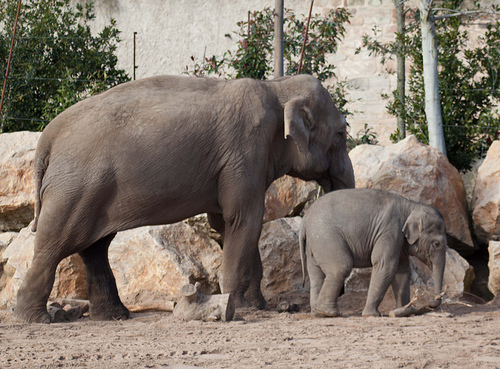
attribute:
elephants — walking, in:
[16, 72, 452, 322]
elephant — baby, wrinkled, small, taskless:
[299, 185, 448, 318]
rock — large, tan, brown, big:
[351, 135, 480, 254]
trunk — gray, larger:
[431, 259, 445, 308]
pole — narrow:
[133, 31, 136, 85]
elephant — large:
[11, 33, 357, 326]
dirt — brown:
[0, 309, 498, 367]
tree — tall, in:
[412, 2, 466, 162]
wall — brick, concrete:
[2, 1, 500, 148]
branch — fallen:
[387, 287, 451, 319]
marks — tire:
[6, 344, 227, 362]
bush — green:
[446, 82, 496, 153]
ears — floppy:
[280, 96, 318, 163]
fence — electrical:
[9, 33, 133, 130]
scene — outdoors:
[15, 72, 492, 333]